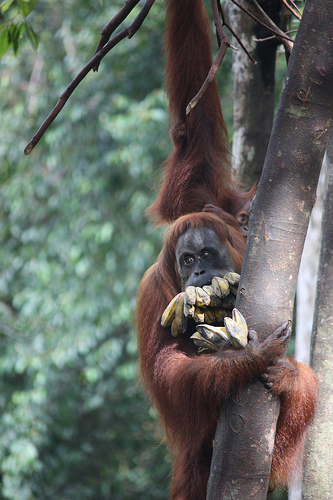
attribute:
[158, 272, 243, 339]
bananas — yellow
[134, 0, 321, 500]
orangutan — furry, red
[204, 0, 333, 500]
tree — tall, thin, smooth, brown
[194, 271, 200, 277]
nostril — large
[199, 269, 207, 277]
nostril — large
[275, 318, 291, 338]
finger — black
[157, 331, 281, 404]
arm — long, furry, red